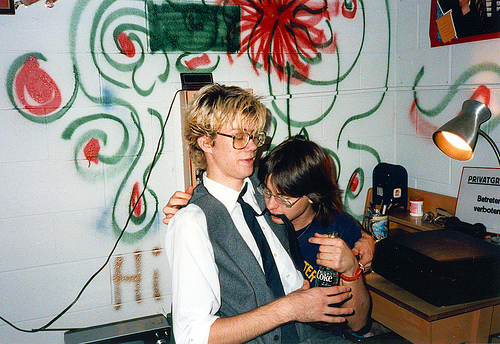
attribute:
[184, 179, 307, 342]
grey vest — gray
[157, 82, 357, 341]
man — light skinned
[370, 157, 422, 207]
container — small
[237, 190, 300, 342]
tie — black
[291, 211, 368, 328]
shirt — blue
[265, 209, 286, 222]
mouth — womans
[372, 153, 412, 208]
mailbox — tiny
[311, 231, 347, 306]
bottle — liquor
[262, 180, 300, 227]
woman's face — womans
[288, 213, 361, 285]
shirt — blue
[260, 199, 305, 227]
mouth — mans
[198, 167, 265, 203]
neck — mans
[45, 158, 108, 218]
brick — white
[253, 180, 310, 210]
glasses — black